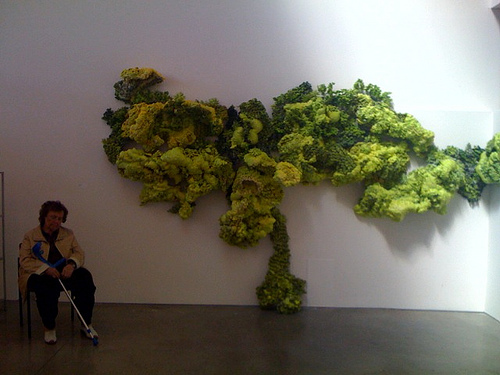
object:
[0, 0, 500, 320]
wall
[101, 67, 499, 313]
art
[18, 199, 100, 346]
woman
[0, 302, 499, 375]
floor